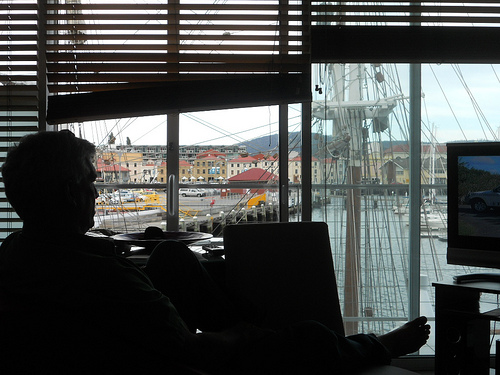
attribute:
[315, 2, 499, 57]
blinds — dark colored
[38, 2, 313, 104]
blinds — dark colored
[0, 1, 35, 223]
blinds — dark colored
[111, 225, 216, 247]
bowl — round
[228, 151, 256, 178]
building — white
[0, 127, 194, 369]
man — dark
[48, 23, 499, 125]
blinds — dark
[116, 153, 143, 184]
building — large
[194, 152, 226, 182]
building — large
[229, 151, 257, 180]
building — large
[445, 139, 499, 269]
tv — small, on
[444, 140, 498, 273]
television — on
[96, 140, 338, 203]
building — many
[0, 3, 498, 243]
blinds — dark colored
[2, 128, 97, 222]
hair — short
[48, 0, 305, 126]
blinds — dark colored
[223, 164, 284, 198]
building — red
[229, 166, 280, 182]
top — red